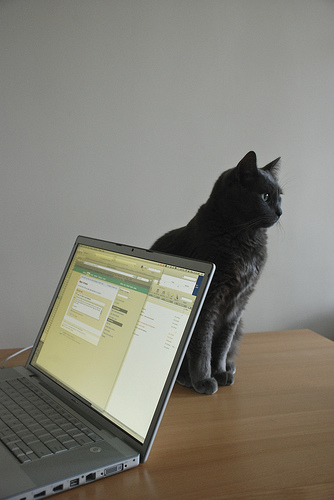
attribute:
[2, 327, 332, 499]
table — this here, wooden, woodgrained patterne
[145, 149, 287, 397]
cat — this here, dark gray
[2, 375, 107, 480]
buttons — these